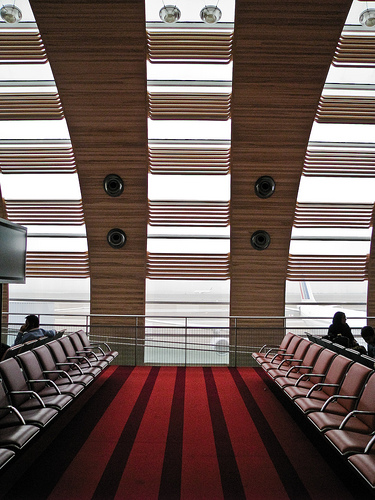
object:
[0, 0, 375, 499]
carpet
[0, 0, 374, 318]
wall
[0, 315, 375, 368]
fence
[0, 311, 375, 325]
pole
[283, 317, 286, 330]
pole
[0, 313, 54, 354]
man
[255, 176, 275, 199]
object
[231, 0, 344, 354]
wood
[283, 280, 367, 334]
plane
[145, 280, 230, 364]
window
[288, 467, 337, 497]
ground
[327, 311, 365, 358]
woman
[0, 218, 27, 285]
tv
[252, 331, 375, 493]
chair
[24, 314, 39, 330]
head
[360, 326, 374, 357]
person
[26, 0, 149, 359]
wood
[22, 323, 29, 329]
cellphone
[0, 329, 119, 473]
chair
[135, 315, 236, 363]
ramp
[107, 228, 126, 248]
object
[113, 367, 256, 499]
floor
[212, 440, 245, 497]
stripes